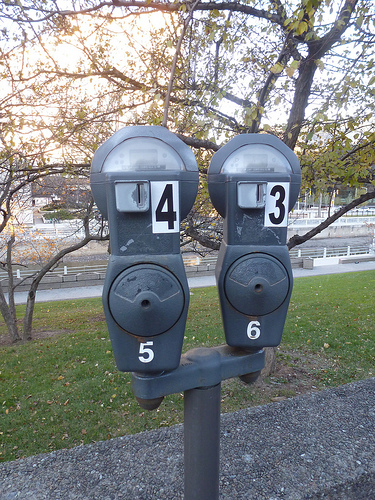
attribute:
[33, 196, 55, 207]
house — white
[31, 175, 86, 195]
roof — black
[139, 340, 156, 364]
number — five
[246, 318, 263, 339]
number — five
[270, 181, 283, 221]
number — five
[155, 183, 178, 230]
number — five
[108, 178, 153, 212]
coin slot — gray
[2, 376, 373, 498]
wall — solid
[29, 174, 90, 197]
roof — black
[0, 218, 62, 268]
leaves — yellow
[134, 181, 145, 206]
slot — coin slot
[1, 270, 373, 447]
grass — green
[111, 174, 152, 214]
slot — coin slot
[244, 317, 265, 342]
number — white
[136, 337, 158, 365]
number — white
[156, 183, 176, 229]
four — number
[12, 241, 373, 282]
fence — long, white